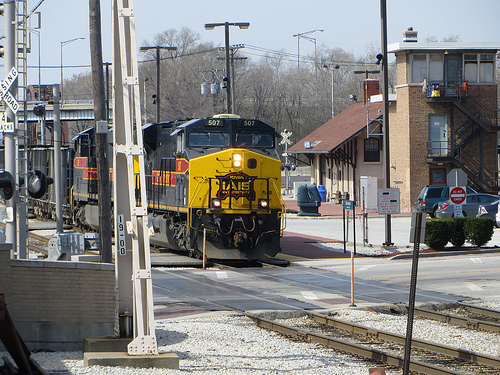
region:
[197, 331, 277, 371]
the stones is white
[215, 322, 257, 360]
the stones is white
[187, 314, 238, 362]
the stones is white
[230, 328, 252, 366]
the stones is white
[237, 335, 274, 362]
the stones is white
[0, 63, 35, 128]
a railroad crossing sign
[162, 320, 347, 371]
white stones beside railroad tracks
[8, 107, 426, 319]
a train approaching a street crossing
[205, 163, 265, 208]
name on front of train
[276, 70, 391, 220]
building with a low roof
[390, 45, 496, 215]
external stairway leading to top floor of building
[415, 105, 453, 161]
a grey metal door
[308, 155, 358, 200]
blue container in front of building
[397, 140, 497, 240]
vehicles parked next to building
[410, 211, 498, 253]
small green bushes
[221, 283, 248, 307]
part of a road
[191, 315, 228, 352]
part of a ground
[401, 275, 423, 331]
part of a post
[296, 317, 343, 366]
edge of a rail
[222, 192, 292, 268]
front of a train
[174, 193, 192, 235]
edge of a train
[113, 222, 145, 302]
part of a number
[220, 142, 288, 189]
the light is yellow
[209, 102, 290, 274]
the light is yellow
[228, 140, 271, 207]
the light is yellow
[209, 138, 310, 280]
Lights on front of train.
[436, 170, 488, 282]
Do not enter sign on side of road.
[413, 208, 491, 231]
Green bushes in parking lot.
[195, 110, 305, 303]
Front of train is yellow.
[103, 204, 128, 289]
White sticker on pole.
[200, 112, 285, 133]
White numbers on front of train.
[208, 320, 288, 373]
Gravel near tracks.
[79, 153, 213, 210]
Red and yellow stripe on side of train.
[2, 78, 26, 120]
White and black railroad crossing sign.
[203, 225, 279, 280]
Bottom of train is black.